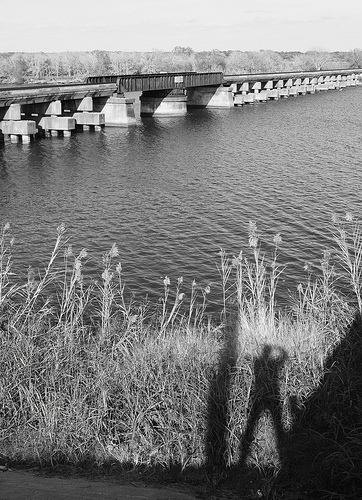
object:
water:
[1, 95, 361, 314]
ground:
[81, 131, 161, 199]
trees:
[173, 296, 238, 465]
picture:
[0, 0, 359, 496]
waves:
[187, 154, 225, 192]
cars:
[122, 69, 138, 89]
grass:
[20, 222, 69, 328]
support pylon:
[39, 102, 75, 139]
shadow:
[239, 338, 289, 464]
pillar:
[138, 90, 188, 117]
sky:
[0, 2, 349, 53]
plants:
[98, 241, 125, 364]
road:
[1, 459, 350, 497]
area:
[2, 49, 361, 86]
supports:
[5, 103, 38, 145]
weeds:
[153, 273, 174, 336]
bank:
[1, 305, 338, 405]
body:
[238, 338, 294, 470]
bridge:
[0, 68, 361, 148]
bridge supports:
[102, 92, 142, 126]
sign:
[173, 73, 184, 86]